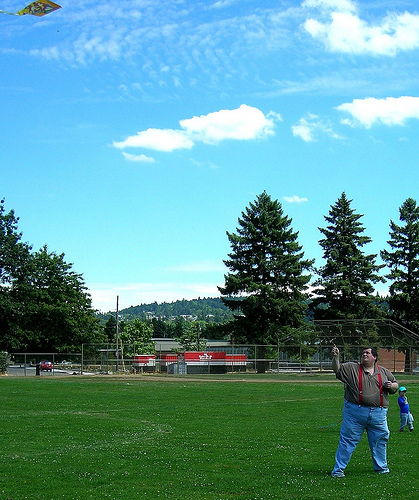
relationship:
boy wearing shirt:
[398, 387, 414, 434] [397, 395, 408, 411]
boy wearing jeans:
[398, 387, 414, 434] [400, 412, 413, 430]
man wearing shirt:
[330, 343, 396, 478] [336, 359, 389, 404]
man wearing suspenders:
[330, 343, 396, 478] [357, 364, 385, 406]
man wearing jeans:
[330, 343, 396, 478] [327, 405, 401, 478]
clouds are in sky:
[115, 9, 417, 161] [1, 1, 418, 303]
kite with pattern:
[2, 1, 61, 21] [28, 2, 38, 15]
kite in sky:
[2, 1, 61, 21] [1, 1, 418, 303]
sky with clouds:
[1, 1, 418, 303] [115, 9, 417, 161]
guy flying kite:
[330, 343, 396, 478] [2, 1, 61, 21]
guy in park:
[330, 343, 396, 478] [3, 192, 417, 490]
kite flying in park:
[2, 1, 61, 21] [3, 192, 417, 490]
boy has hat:
[398, 387, 414, 434] [400, 387, 406, 390]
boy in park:
[398, 387, 414, 434] [3, 192, 417, 490]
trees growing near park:
[219, 192, 418, 372] [3, 192, 417, 490]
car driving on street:
[39, 361, 53, 371] [9, 352, 84, 380]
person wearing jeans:
[330, 343, 396, 478] [327, 405, 401, 478]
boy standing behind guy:
[398, 387, 414, 434] [330, 343, 396, 478]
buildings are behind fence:
[136, 351, 247, 373] [6, 343, 418, 374]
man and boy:
[330, 343, 396, 478] [398, 387, 414, 434]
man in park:
[330, 343, 396, 478] [3, 192, 417, 490]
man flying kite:
[330, 343, 396, 478] [2, 1, 61, 21]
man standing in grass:
[330, 343, 396, 478] [3, 376, 418, 499]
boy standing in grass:
[326, 343, 401, 483] [3, 376, 418, 499]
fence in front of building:
[6, 343, 418, 374] [136, 351, 247, 373]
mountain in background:
[105, 293, 418, 320] [2, 242, 417, 343]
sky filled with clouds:
[1, 1, 418, 303] [115, 9, 417, 161]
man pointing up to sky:
[330, 343, 396, 478] [1, 1, 418, 303]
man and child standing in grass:
[327, 343, 419, 487] [3, 376, 418, 499]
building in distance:
[136, 351, 247, 373] [4, 309, 417, 382]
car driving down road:
[39, 361, 53, 371] [4, 363, 67, 375]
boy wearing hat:
[398, 387, 414, 434] [400, 387, 406, 390]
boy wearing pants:
[398, 387, 414, 434] [400, 412, 413, 430]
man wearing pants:
[330, 343, 396, 478] [327, 405, 401, 478]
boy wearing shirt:
[326, 343, 401, 483] [336, 359, 389, 404]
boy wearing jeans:
[326, 343, 401, 483] [327, 405, 401, 478]